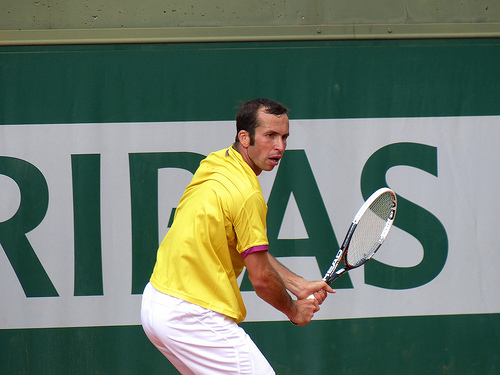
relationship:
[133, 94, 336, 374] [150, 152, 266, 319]
man wearing a t-shirt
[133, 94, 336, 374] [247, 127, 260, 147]
man has sideburn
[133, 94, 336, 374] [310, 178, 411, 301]
man holding racket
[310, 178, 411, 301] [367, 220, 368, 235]
racket for tennis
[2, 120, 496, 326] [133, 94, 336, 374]
sign behind man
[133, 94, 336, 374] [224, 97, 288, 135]
man has brown hair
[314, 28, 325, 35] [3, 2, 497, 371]
bolt on wall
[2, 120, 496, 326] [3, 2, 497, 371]
sign on wall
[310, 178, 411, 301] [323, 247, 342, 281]
racket has writing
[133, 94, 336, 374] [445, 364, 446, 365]
man ready to hit ball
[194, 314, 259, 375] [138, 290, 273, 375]
seam on pants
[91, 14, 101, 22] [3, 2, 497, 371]
hole in wall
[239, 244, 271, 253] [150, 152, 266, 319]
pink on t-shirt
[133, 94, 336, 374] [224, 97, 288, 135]
man has hair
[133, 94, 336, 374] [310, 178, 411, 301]
man has racket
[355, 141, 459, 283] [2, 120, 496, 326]
s on sign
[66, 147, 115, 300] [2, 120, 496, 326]
i on sign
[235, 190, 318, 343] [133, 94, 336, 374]
right arm of man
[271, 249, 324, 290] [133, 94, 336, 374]
left arm of man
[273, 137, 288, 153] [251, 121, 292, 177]
nose on face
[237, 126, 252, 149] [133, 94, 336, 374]
ear of man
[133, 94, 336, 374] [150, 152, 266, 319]
man wears t-shirt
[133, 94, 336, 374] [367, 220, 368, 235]
man playing tennis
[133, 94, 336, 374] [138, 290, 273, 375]
man has pants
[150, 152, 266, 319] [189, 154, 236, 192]
t-shirt has wrinkles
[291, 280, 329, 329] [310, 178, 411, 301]
hands on racket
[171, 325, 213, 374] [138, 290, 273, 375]
wrinkles in pants